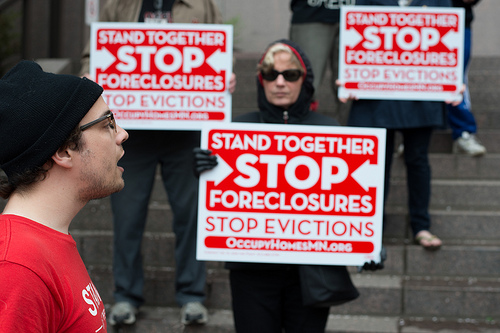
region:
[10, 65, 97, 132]
Black color hat head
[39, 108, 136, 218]
Man with glasses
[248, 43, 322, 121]
Blonde woman with sunglasses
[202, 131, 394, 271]
Protest sign red and white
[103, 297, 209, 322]
Tennis gray standing on the floor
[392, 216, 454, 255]
Women flip flops on the stairs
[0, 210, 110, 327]
Red shirt man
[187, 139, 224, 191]
Glove black woman holding banner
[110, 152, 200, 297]
Dark gray pants man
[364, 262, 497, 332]
gray stairs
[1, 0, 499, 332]
A photo of a protest.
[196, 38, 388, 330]
A woman in shades holding a picket sign.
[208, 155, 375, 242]
The sign to Stop Foreclosures.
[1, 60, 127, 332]
A dark haired young man speaking.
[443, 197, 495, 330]
The grey cement stairs.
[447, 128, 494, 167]
A protestor's white sneaker.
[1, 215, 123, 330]
The lead protestor's red shirt.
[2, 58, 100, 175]
The man's black hat.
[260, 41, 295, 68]
The woman's blonde bangs.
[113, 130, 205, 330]
The person's dark colored pants.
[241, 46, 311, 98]
Woman with sunglasses on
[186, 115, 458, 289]
Person holding a sign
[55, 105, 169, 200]
Man with mouth open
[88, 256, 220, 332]
Person standing on steps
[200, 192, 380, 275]
Stop evictions sign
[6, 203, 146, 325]
Man wearing red shirt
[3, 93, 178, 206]
Man wearing a beanie hat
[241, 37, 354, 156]
Woman has a hood up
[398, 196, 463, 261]
Person wearing flip flops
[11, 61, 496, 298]
People standing outside on steps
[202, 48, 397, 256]
woman carrying red and white sign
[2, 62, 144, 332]
man standing with the protesters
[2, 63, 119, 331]
man wearing black hat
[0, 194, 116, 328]
man wearing red t shirt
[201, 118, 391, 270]
sign says stand together stop forclosures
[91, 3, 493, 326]
several people standing on the steps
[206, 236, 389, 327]
woman wearing black pants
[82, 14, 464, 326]
three people holding signs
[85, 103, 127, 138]
man wearing glasses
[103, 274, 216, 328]
man wearing grey tennis shoes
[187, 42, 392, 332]
a blond carrying a sign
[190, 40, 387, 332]
a woman wearing sunglasses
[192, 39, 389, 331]
a person with no economic sense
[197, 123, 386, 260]
a sign composed by a liberal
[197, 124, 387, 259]
a sign composed by someone who has never loaned money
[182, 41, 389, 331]
a woman wearing sunglasses as a disguise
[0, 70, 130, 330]
a young man about to sneeze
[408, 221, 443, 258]
a person with no shoes on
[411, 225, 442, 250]
a foot marching in flip-flops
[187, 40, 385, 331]
someone who favors unlawful taking of property